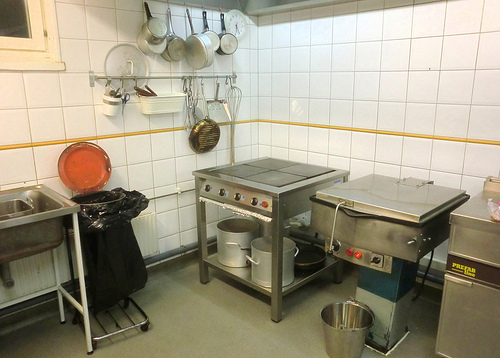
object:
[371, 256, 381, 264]
knob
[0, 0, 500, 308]
wall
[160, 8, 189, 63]
pans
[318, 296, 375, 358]
pail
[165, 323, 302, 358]
floor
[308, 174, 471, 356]
stove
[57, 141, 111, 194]
plate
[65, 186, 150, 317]
bag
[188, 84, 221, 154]
skillet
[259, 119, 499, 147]
line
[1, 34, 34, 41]
edge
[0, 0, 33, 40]
window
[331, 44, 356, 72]
tiles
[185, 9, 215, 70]
pot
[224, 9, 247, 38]
clock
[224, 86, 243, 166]
whisk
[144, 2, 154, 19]
hadle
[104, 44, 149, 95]
lid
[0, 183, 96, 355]
sik